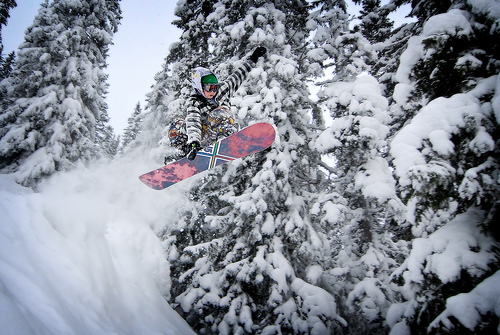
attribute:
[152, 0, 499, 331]
tree — green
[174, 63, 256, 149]
coat — black and white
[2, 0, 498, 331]
snow — white, evergreen 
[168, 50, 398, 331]
tree — green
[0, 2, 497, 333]
trees — snow covered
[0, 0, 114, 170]
snow — white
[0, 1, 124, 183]
tree — green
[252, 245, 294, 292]
snow — white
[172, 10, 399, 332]
tree — green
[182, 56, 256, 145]
jacket —  striped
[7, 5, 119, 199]
snowy pine — tall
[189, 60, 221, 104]
person — snowboarding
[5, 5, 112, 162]
tree — green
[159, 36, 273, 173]
person — wearing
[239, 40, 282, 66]
mittens — black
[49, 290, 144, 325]
snow — white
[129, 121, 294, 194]
snowboard — red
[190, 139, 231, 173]
design — colorful 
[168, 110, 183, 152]
leg — bent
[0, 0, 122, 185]
snow — white